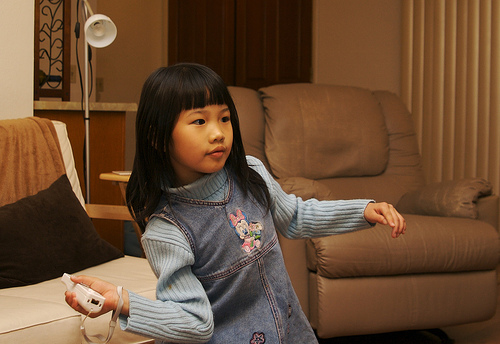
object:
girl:
[64, 63, 405, 344]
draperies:
[397, 0, 499, 183]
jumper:
[146, 171, 320, 344]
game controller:
[59, 272, 110, 316]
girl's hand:
[63, 274, 120, 317]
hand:
[364, 201, 408, 238]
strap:
[78, 284, 124, 343]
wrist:
[111, 286, 127, 312]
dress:
[117, 153, 373, 343]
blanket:
[0, 115, 127, 292]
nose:
[208, 126, 225, 144]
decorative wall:
[32, 2, 73, 102]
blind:
[400, 0, 496, 188]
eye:
[189, 116, 207, 126]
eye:
[219, 114, 231, 124]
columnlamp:
[71, 0, 117, 207]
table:
[83, 170, 147, 260]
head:
[134, 62, 234, 173]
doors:
[168, 0, 316, 92]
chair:
[258, 82, 498, 339]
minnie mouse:
[226, 206, 262, 254]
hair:
[126, 62, 273, 230]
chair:
[0, 117, 164, 344]